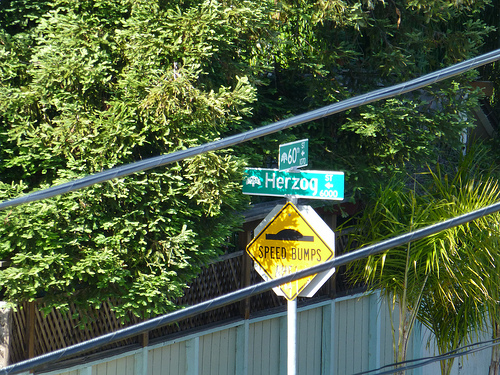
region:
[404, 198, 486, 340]
top of green palm trees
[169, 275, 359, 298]
portion of blue street railing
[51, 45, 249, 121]
large area of green trees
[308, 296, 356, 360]
blue post on large fence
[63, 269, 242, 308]
iron barrier in front of fence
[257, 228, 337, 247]
black object on yellow sign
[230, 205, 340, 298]
square yellow sign on post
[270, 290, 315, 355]
white paint on post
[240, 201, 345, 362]
white post on side of the road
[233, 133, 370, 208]
green and white street sign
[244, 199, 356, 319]
yellow speed bump sign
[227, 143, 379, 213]
two green street id signs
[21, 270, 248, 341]
brown wooden fence under the tree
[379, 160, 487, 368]
palm tree in the distance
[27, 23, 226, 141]
green tree with lots of leaves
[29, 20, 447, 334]
road signs by the side of road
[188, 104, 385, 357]
yellow and green road signs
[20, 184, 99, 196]
metal pole boundary on the side of road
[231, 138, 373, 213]
street sign on the road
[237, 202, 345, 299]
yellow diagonal street sign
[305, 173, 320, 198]
white letter on a sign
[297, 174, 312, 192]
white letter on a sign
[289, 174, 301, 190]
white letter on a sign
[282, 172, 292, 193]
white letter on a sign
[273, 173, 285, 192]
white letter on a sign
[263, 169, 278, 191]
white letter on a sign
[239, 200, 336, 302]
yellow sign on a pole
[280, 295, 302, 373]
silver pole holding a sign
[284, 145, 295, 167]
white number on a sign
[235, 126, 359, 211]
green street signs on a pole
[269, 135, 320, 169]
Green and white sign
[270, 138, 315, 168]
Sign with the number 60 on it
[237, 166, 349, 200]
Green and white sign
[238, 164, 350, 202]
Sign with the word Herzog on it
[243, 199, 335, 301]
Yellow and black diamond sign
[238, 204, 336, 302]
Sign with the words "Speed Bumps Ahead"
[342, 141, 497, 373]
Bright green palm trees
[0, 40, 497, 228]
Black telephone wire above the signs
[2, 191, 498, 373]
Black telephone wires below the signs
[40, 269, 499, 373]
White wooden fencing below the signs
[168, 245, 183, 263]
part of a branch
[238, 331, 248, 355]
part of a wall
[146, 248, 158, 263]
part of a fence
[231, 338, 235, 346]
edge of a fence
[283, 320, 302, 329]
part of a pole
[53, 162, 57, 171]
part of a leaf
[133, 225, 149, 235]
part of a branch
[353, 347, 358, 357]
part of a fence